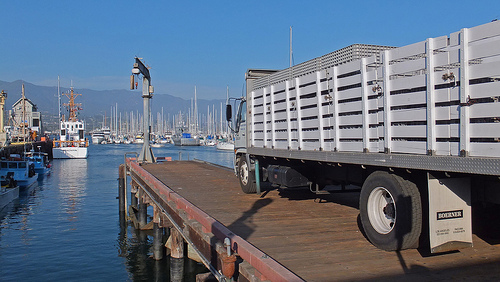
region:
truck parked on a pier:
[220, 78, 405, 213]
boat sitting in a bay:
[36, 92, 99, 164]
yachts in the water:
[89, 123, 106, 147]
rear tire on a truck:
[335, 165, 425, 254]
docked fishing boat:
[42, 88, 96, 160]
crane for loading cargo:
[97, 46, 184, 181]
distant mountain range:
[1, 56, 153, 116]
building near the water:
[11, 90, 48, 144]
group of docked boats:
[90, 102, 234, 159]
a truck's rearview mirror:
[205, 96, 242, 131]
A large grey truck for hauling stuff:
[226, 18, 498, 246]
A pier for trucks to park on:
[116, 150, 498, 278]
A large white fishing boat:
[47, 80, 88, 163]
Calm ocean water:
[2, 85, 275, 275]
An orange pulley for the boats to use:
[116, 52, 160, 132]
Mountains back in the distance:
[3, 76, 266, 137]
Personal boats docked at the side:
[2, 144, 62, 199]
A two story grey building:
[12, 90, 44, 148]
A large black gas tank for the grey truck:
[259, 152, 361, 199]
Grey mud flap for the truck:
[406, 156, 483, 269]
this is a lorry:
[237, 63, 492, 216]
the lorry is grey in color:
[236, 45, 498, 213]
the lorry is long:
[227, 16, 498, 226]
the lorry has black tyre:
[355, 173, 418, 247]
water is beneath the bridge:
[0, 238, 132, 275]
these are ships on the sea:
[89, 108, 213, 145]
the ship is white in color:
[55, 123, 89, 154]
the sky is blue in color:
[5, 0, 478, 18]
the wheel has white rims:
[371, 191, 389, 228]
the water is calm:
[30, 198, 93, 265]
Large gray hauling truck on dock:
[228, 87, 492, 190]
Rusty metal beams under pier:
[112, 157, 210, 257]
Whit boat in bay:
[51, 100, 112, 182]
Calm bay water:
[45, 179, 112, 280]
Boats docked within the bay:
[98, 107, 227, 157]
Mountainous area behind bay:
[14, 69, 109, 120]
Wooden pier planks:
[175, 165, 232, 206]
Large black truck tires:
[353, 175, 432, 253]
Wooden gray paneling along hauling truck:
[238, 81, 463, 157]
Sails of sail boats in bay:
[177, 87, 211, 134]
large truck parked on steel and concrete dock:
[189, 22, 495, 258]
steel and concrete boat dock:
[73, 157, 238, 268]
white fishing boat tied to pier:
[41, 78, 96, 169]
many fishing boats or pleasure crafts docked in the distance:
[87, 90, 231, 153]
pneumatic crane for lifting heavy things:
[109, 44, 181, 176]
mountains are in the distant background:
[5, 71, 220, 114]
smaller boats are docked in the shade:
[0, 144, 67, 211]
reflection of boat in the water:
[49, 158, 98, 243]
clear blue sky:
[26, 4, 265, 63]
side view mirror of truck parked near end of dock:
[207, 71, 262, 153]